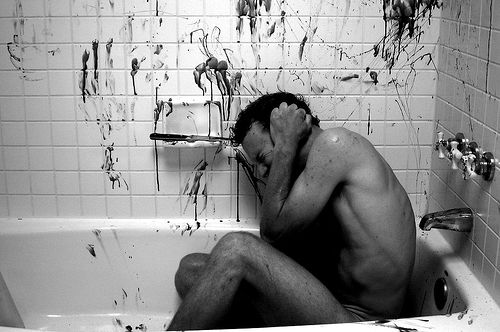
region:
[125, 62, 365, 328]
man naked in a tub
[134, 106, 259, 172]
knife on a soap dish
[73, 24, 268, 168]
blood on the walls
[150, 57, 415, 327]
distraught man in a bathtub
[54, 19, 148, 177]
bloody hand prints on wall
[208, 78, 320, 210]
man holding his head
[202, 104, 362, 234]
man with dark hair in bathtub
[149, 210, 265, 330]
man with hairy legs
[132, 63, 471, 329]
guy naked in a tub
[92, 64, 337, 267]
knife in a bathtub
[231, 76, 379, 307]
A man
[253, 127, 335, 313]
A man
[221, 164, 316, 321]
A man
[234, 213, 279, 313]
A man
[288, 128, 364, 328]
A man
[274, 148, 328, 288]
A man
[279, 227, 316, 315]
A man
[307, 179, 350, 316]
A man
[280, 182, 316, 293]
A man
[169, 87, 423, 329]
A man committing suicide.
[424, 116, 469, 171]
a hot water faucet.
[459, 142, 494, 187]
a cold water faucet.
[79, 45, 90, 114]
a spatter of blood on a wall.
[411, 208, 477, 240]
a water faucet.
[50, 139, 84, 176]
a tile in a bathroom.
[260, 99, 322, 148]
a person's clenched hand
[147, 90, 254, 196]
a knife in a soap dish.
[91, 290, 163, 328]
the bottom of a bath tub.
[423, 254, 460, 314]
an overflow drain.